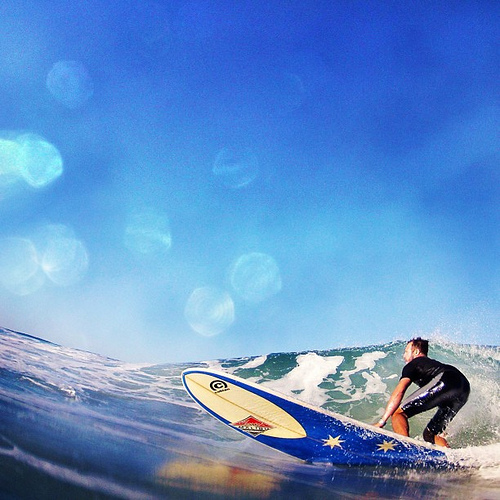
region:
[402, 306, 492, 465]
surfer wearing a wet suit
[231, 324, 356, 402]
foam on the water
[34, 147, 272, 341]
water on the camera lens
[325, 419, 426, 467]
stars on the bottom of surfboard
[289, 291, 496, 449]
riding the wave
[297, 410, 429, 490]
blue on the bottom of surfboard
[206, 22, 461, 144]
sky is clear bright blue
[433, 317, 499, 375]
splash at top of wave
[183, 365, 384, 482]
yellow line down the middle of surfboard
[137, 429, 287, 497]
surfboard reflection in the water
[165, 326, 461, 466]
A man surfing on water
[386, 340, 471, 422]
A man in black wet suit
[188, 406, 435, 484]
Blue and cream surf broad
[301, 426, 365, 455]
Stars on a surf broad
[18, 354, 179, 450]
waves in the water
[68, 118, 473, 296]
A clear blue sky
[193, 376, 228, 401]
The letter c on surf broad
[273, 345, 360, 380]
White foam on the water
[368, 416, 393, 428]
A watch on surfer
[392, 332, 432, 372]
A surfers head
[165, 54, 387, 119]
Sky is blue color.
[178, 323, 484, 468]
One man is surfing.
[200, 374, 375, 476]
Surf board is blue and white color.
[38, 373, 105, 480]
Water is blue color.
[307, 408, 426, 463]
Star design in surf board.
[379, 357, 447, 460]
Man is wearing black suit.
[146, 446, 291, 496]
Reflection is seen on water.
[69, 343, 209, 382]
Waves are white color.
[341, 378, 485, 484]
Man is standing in water.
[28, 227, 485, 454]
Day time picture.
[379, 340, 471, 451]
the surfer is wearing a wetsuit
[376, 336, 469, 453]
the surfer is kneeling down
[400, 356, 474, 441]
the wetsuit is black in color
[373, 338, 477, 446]
the surfer is wet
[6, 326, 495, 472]
ocean waves are rising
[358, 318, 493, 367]
the water is splashing about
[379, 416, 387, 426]
the surfer is wearing wrist band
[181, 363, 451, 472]
the surfboard is above the water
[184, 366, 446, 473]
the surfboard is yellow and blue underneath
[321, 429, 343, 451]
the surfboard has a star symbol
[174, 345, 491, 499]
blue and white surfboard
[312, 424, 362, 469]
white star on a blue surfboard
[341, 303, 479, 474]
a man surfing on the water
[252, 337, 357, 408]
white foaming ocean water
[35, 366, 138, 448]
dark blue ocean water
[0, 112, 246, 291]
light blue sky above the ocean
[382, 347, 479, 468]
black wet suit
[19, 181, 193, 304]
light reflecting on the blue sky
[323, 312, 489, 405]
wave in the water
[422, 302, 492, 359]
white water spraying